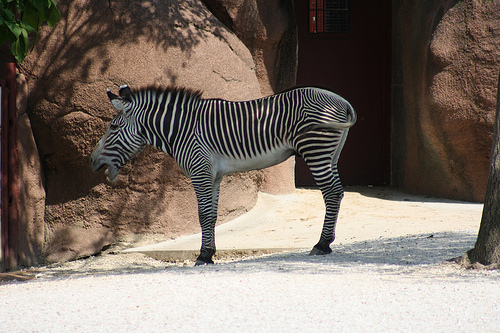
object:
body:
[172, 89, 352, 266]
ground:
[1, 188, 500, 333]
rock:
[418, 2, 499, 201]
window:
[308, 7, 338, 30]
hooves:
[195, 253, 209, 265]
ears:
[119, 85, 131, 101]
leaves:
[3, 1, 28, 49]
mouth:
[92, 163, 111, 182]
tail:
[303, 105, 357, 132]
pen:
[0, 0, 497, 284]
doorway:
[293, 1, 399, 191]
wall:
[8, 2, 264, 242]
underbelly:
[216, 146, 291, 177]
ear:
[106, 89, 128, 110]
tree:
[475, 149, 499, 264]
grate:
[213, 250, 247, 261]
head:
[91, 85, 151, 180]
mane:
[131, 84, 203, 96]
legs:
[212, 178, 219, 251]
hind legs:
[302, 143, 344, 255]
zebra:
[92, 85, 353, 264]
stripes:
[299, 144, 337, 153]